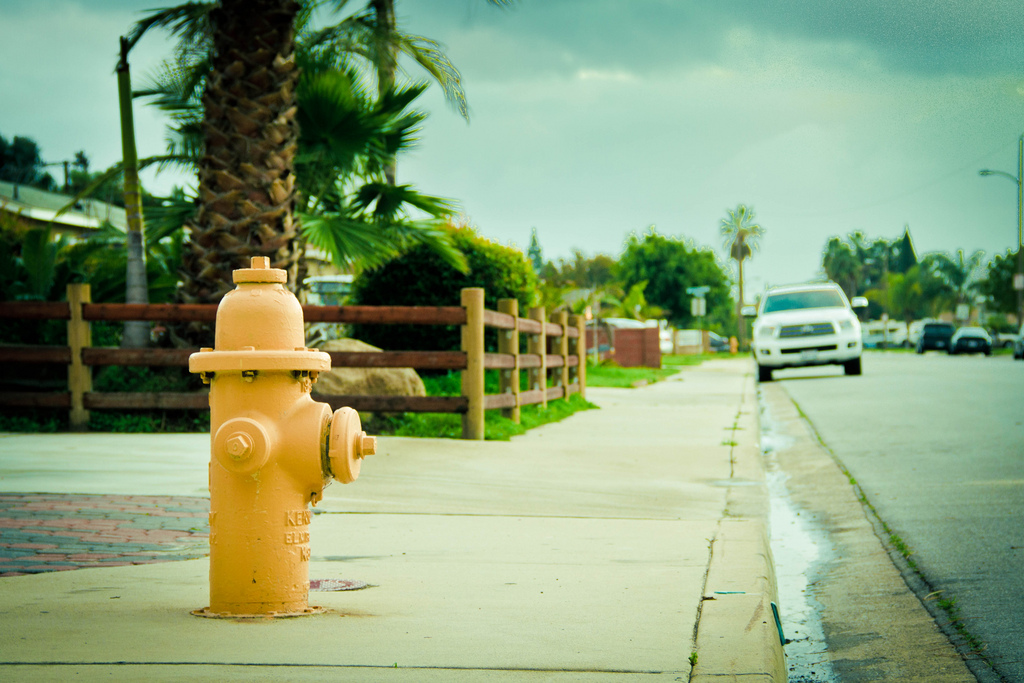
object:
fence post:
[47, 273, 130, 448]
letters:
[279, 505, 298, 527]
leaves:
[301, 206, 401, 274]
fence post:
[443, 270, 504, 459]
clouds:
[518, 14, 1024, 163]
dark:
[698, 175, 970, 243]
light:
[942, 146, 1022, 238]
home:
[2, 160, 223, 363]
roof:
[0, 176, 159, 229]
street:
[756, 323, 1024, 670]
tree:
[57, 0, 480, 393]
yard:
[3, 192, 598, 445]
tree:
[601, 221, 737, 346]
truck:
[713, 256, 900, 421]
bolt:
[342, 422, 402, 465]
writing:
[266, 495, 320, 565]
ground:
[0, 329, 1017, 683]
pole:
[1009, 130, 1024, 255]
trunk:
[143, 64, 375, 398]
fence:
[0, 278, 596, 429]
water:
[748, 500, 852, 683]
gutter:
[745, 366, 996, 679]